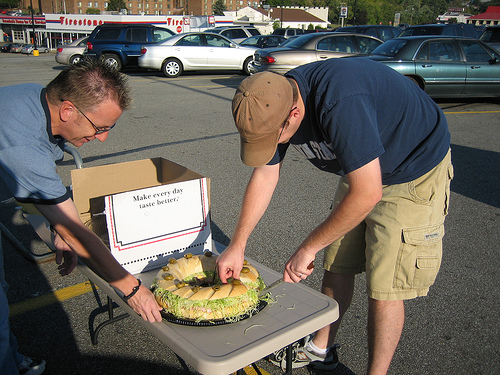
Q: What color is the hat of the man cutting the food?
A: Brown.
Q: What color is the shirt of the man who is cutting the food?
A: Blue.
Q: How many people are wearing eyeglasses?
A: Two.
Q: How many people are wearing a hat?
A: One.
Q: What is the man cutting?
A: A sandwich.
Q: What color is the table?
A: Beige.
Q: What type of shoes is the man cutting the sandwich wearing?
A: Sneakers.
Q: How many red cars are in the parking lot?
A: Zero.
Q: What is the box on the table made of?
A: Cardboard.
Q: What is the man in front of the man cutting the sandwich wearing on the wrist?
A: Bracelet.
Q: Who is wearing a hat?
A: Man on right.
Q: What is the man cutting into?
A: A sandwich.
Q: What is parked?
A: Cars.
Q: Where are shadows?
A: On the ground.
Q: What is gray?
A: Table.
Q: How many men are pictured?
A: Two.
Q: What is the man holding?
A: A knife.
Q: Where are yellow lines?
A: On the ground.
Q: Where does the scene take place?
A: In a parking lot.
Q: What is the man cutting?
A: A sandwich.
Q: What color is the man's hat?
A: Brown.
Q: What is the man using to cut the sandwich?
A: A knife.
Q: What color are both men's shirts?
A: Blue.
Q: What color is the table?
A: Grey.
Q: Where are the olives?
A: On the sandwich.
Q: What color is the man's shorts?
A: Tan.